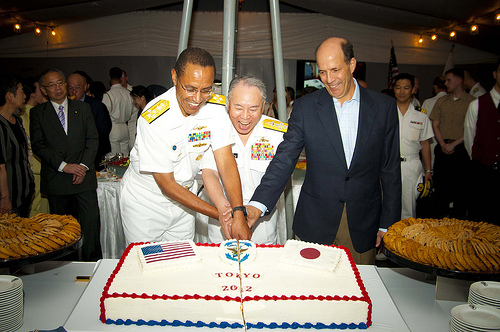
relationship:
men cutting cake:
[161, 54, 380, 229] [121, 246, 362, 323]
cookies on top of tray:
[406, 242, 446, 263] [378, 237, 500, 283]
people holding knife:
[10, 84, 119, 209] [229, 239, 246, 265]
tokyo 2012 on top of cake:
[207, 273, 257, 294] [121, 246, 362, 323]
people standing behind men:
[10, 84, 119, 209] [161, 54, 380, 229]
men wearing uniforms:
[161, 54, 380, 229] [143, 117, 273, 218]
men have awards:
[161, 54, 380, 229] [246, 139, 275, 163]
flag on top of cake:
[138, 237, 203, 274] [121, 246, 362, 323]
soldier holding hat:
[434, 64, 471, 211] [418, 174, 435, 199]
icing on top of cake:
[159, 321, 189, 324] [121, 246, 362, 323]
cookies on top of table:
[406, 242, 446, 263] [32, 285, 59, 319]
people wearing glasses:
[29, 68, 103, 262] [37, 78, 65, 90]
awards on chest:
[246, 139, 275, 163] [177, 118, 201, 176]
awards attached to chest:
[246, 139, 275, 163] [177, 118, 201, 176]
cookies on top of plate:
[406, 242, 446, 263] [470, 281, 494, 294]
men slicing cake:
[161, 54, 380, 229] [121, 246, 362, 323]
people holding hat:
[29, 68, 103, 262] [418, 174, 435, 199]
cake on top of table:
[121, 246, 362, 323] [32, 285, 59, 319]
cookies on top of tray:
[406, 242, 446, 263] [394, 263, 468, 282]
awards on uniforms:
[246, 139, 275, 163] [143, 117, 273, 218]